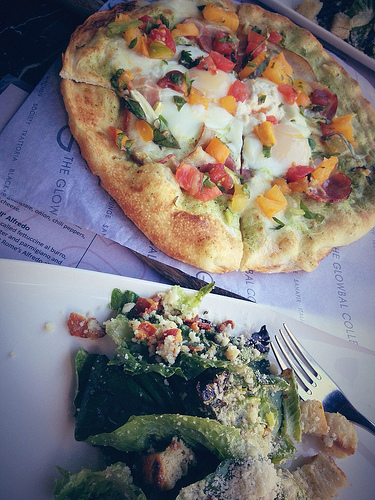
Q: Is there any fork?
A: Yes, there is a fork.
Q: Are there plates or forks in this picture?
A: Yes, there is a fork.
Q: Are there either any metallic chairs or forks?
A: Yes, there is a metal fork.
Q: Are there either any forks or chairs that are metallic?
A: Yes, the fork is metallic.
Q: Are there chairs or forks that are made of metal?
A: Yes, the fork is made of metal.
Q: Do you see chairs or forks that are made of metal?
A: Yes, the fork is made of metal.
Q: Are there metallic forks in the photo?
A: Yes, there is a metal fork.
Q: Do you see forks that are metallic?
A: Yes, there is a fork that is metallic.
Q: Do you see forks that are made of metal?
A: Yes, there is a fork that is made of metal.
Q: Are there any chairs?
A: No, there are no chairs.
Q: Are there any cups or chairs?
A: No, there are no chairs or cups.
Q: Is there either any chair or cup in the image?
A: No, there are no chairs or cups.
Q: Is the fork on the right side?
A: Yes, the fork is on the right of the image.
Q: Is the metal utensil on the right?
A: Yes, the fork is on the right of the image.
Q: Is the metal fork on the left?
A: No, the fork is on the right of the image.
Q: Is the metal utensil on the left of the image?
A: No, the fork is on the right of the image.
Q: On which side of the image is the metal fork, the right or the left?
A: The fork is on the right of the image.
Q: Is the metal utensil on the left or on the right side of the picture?
A: The fork is on the right of the image.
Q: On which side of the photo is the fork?
A: The fork is on the right of the image.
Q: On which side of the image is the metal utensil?
A: The fork is on the right of the image.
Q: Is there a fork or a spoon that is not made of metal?
A: No, there is a fork but it is made of metal.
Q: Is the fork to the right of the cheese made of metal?
A: Yes, the fork is made of metal.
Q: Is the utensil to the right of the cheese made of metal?
A: Yes, the fork is made of metal.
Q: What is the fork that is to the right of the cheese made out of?
A: The fork is made of metal.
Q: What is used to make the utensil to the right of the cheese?
A: The fork is made of metal.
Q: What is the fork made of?
A: The fork is made of metal.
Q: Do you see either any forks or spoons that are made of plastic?
A: No, there is a fork but it is made of metal.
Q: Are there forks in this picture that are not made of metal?
A: No, there is a fork but it is made of metal.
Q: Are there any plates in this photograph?
A: Yes, there is a plate.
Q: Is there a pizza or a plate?
A: Yes, there is a plate.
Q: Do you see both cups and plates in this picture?
A: No, there is a plate but no cups.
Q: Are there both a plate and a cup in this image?
A: No, there is a plate but no cups.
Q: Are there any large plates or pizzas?
A: Yes, there is a large plate.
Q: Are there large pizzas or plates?
A: Yes, there is a large plate.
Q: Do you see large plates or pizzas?
A: Yes, there is a large plate.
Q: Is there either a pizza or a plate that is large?
A: Yes, the plate is large.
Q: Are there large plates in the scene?
A: Yes, there is a large plate.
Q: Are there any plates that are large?
A: Yes, there is a plate that is large.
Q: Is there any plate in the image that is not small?
A: Yes, there is a large plate.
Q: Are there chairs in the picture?
A: No, there are no chairs.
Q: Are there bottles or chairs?
A: No, there are no chairs or bottles.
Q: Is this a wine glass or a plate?
A: This is a plate.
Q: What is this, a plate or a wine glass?
A: This is a plate.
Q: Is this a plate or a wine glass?
A: This is a plate.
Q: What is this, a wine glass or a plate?
A: This is a plate.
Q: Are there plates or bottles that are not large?
A: No, there is a plate but it is large.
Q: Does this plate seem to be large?
A: Yes, the plate is large.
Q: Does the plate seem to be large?
A: Yes, the plate is large.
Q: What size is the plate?
A: The plate is large.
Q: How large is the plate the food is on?
A: The plate is large.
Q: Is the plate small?
A: No, the plate is large.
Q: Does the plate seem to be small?
A: No, the plate is large.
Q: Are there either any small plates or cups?
A: No, there is a plate but it is large.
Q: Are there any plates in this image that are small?
A: No, there is a plate but it is large.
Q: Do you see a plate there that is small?
A: No, there is a plate but it is large.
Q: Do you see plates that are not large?
A: No, there is a plate but it is large.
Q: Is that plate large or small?
A: The plate is large.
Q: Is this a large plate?
A: Yes, this is a large plate.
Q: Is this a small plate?
A: No, this is a large plate.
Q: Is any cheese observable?
A: Yes, there is cheese.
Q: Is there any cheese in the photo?
A: Yes, there is cheese.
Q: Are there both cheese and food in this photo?
A: Yes, there are both cheese and food.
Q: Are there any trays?
A: No, there are no trays.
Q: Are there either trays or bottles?
A: No, there are no trays or bottles.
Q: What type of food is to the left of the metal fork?
A: The food is cheese.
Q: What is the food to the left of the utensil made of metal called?
A: The food is cheese.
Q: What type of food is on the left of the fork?
A: The food is cheese.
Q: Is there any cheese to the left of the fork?
A: Yes, there is cheese to the left of the fork.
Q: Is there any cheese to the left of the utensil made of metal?
A: Yes, there is cheese to the left of the fork.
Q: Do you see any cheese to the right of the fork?
A: No, the cheese is to the left of the fork.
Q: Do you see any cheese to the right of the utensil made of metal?
A: No, the cheese is to the left of the fork.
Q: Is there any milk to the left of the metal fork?
A: No, there is cheese to the left of the fork.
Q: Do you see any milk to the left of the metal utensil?
A: No, there is cheese to the left of the fork.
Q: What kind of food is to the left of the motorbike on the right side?
A: The food is cheese.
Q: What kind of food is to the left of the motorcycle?
A: The food is cheese.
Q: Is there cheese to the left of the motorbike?
A: Yes, there is cheese to the left of the motorbike.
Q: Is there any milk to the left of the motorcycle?
A: No, there is cheese to the left of the motorcycle.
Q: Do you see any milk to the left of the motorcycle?
A: No, there is cheese to the left of the motorcycle.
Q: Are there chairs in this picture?
A: No, there are no chairs.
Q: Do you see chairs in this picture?
A: No, there are no chairs.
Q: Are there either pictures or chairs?
A: No, there are no chairs or pictures.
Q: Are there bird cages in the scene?
A: No, there are no bird cages.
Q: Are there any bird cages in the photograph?
A: No, there are no bird cages.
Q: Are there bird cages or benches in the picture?
A: No, there are no bird cages or benches.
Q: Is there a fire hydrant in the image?
A: No, there are no fire hydrants.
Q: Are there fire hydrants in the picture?
A: No, there are no fire hydrants.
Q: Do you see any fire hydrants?
A: No, there are no fire hydrants.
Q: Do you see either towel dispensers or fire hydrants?
A: No, there are no fire hydrants or towel dispensers.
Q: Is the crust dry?
A: Yes, the crust is dry.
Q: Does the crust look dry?
A: Yes, the crust is dry.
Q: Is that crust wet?
A: No, the crust is dry.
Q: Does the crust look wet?
A: No, the crust is dry.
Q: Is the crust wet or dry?
A: The crust is dry.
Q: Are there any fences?
A: No, there are no fences.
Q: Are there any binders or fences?
A: No, there are no fences or binders.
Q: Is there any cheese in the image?
A: Yes, there is cheese.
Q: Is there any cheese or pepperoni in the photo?
A: Yes, there is cheese.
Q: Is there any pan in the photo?
A: No, there are no pans.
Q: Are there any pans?
A: No, there are no pans.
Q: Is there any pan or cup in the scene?
A: No, there are no pans or cups.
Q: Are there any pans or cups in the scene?
A: No, there are no pans or cups.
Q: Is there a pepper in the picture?
A: Yes, there is a pepper.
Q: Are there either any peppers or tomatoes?
A: Yes, there is a pepper.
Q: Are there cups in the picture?
A: No, there are no cups.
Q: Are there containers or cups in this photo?
A: No, there are no cups or containers.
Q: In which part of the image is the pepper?
A: The pepper is on the right of the image.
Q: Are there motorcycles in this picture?
A: Yes, there is a motorcycle.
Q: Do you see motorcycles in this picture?
A: Yes, there is a motorcycle.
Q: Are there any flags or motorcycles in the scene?
A: Yes, there is a motorcycle.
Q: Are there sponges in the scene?
A: No, there are no sponges.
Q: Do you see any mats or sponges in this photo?
A: No, there are no sponges or mats.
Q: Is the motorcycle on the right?
A: Yes, the motorcycle is on the right of the image.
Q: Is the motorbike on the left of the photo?
A: No, the motorbike is on the right of the image.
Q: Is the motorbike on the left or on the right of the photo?
A: The motorbike is on the right of the image.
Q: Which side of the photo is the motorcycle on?
A: The motorcycle is on the right of the image.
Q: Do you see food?
A: Yes, there is food.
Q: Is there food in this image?
A: Yes, there is food.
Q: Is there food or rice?
A: Yes, there is food.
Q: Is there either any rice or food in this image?
A: Yes, there is food.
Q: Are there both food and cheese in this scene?
A: Yes, there are both food and cheese.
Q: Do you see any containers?
A: No, there are no containers.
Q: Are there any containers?
A: No, there are no containers.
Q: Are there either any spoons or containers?
A: No, there are no containers or spoons.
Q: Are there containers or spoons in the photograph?
A: No, there are no containers or spoons.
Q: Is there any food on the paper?
A: Yes, there is food on the paper.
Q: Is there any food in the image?
A: Yes, there is food.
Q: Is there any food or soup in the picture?
A: Yes, there is food.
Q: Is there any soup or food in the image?
A: Yes, there is food.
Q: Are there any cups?
A: No, there are no cups.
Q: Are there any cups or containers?
A: No, there are no cups or containers.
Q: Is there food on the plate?
A: Yes, there is food on the plate.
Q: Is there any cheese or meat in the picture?
A: Yes, there is cheese.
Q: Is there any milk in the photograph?
A: No, there is no milk.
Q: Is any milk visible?
A: No, there is no milk.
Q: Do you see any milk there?
A: No, there is no milk.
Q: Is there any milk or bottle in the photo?
A: No, there are no milk or bottles.